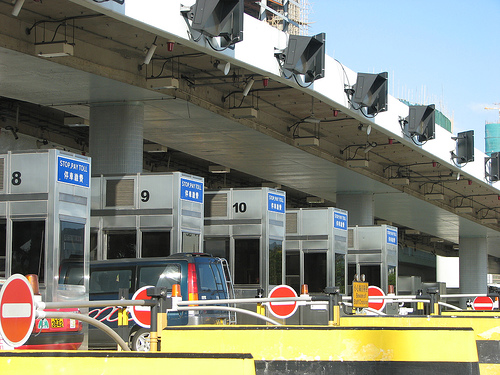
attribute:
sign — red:
[2, 276, 36, 366]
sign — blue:
[53, 150, 118, 199]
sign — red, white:
[1, 271, 33, 341]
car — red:
[13, 286, 104, 354]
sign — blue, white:
[62, 153, 94, 182]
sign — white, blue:
[171, 175, 219, 215]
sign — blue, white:
[261, 188, 288, 218]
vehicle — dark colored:
[104, 254, 219, 310]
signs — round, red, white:
[7, 275, 496, 315]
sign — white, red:
[263, 278, 310, 320]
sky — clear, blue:
[332, 18, 432, 67]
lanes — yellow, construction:
[109, 304, 230, 373]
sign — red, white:
[267, 284, 311, 317]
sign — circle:
[0, 273, 43, 337]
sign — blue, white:
[54, 159, 101, 183]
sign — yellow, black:
[350, 279, 374, 306]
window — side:
[95, 265, 128, 292]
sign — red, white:
[3, 272, 33, 352]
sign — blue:
[171, 171, 207, 202]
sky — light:
[316, 10, 475, 156]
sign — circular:
[475, 287, 486, 316]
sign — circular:
[258, 278, 321, 328]